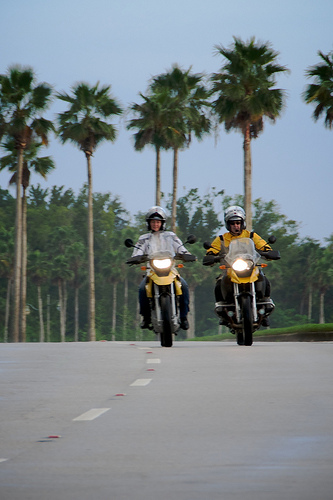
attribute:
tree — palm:
[206, 32, 290, 228]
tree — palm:
[158, 58, 214, 229]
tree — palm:
[121, 87, 162, 205]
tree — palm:
[1, 61, 59, 341]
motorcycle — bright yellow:
[121, 231, 198, 345]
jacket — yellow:
[204, 229, 273, 286]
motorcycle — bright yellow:
[198, 231, 282, 349]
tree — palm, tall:
[48, 74, 126, 342]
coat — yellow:
[199, 223, 278, 288]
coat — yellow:
[200, 224, 273, 293]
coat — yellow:
[198, 226, 280, 284]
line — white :
[69, 400, 124, 432]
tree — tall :
[48, 72, 135, 343]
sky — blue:
[1, 1, 331, 249]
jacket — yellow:
[202, 226, 277, 288]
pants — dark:
[134, 259, 196, 333]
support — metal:
[247, 280, 263, 328]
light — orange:
[252, 260, 268, 270]